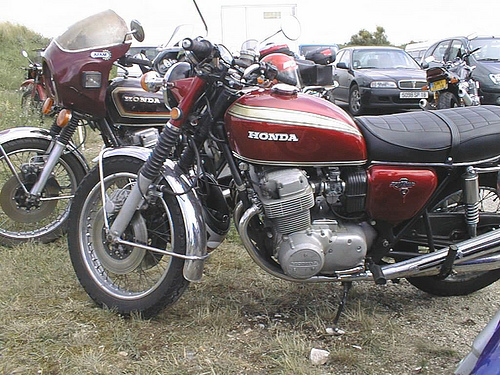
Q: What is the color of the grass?
A: Grass.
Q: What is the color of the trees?
A: Green.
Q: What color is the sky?
A: White.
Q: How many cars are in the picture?
A: Two cars.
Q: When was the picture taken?
A: During the daytime.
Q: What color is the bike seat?
A: Black.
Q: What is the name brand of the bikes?
A: Honda.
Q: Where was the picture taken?
A: In a parking lot.